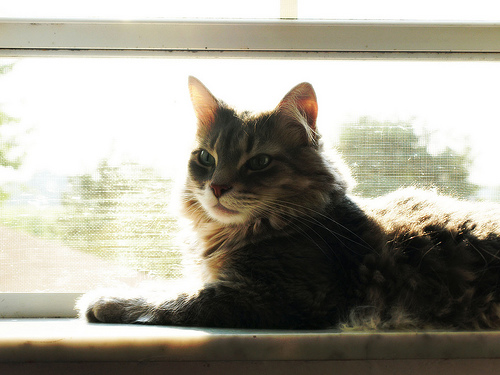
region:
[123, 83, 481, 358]
Cat is sitting in window sill.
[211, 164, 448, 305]
cat is grey color.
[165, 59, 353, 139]
Two pointed ears for cat.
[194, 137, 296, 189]
Eyes are yellow color.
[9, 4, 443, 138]
Window frame is white color.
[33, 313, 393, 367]
Window sill is white color.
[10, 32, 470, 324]
Sunlight passes through the window.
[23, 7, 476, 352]
Day time picture.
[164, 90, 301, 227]
Cat is looking left.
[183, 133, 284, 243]
Cat mouth is closed.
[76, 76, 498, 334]
The cat is sitting in the window.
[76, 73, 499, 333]
The cat has long fur.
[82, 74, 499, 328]
The cat is gray, white and black.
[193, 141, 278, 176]
The cat has green eyes.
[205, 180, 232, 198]
The cat has a pink nose.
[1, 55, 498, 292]
Trees can be seen outside the window.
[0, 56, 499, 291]
The trees are green.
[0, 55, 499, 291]
The trees have leaves.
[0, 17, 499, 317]
The window is white.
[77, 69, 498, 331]
The cat is laying in the window.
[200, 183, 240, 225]
all white and furry cat's muzzle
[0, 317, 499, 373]
white and gray marbleized sill for the cat to chillax on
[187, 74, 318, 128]
cat's ears perked and listening intently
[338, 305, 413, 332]
white belly fur that does not look like it belongs to the cat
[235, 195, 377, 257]
long whiskers on a cat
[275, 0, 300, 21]
window lock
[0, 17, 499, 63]
white window ledge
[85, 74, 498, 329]
calico cat with white muzzle and white belly fur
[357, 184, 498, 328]
longer hairs on the cat compared to the shorter ones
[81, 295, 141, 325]
lighter colored cat paw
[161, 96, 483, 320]
Cat is grey color.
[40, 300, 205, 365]
Window sill is white color.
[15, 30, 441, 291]
Sunlight is passing through the window.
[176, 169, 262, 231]
Cat mouth is closed.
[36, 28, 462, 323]
Day time picture.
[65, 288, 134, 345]
Claws are grey color.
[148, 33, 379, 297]
the face of a cat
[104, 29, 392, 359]
this is a house cat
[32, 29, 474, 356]
the cat sits in the window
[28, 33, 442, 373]
the cat enjoys the sun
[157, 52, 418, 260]
sunlight streams through the window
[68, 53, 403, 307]
the cat's ears glow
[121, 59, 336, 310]
the cat has tabby markings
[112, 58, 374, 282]
the cat has a pink nose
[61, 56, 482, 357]
the cat is alert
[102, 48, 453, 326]
the cat's ears are pink